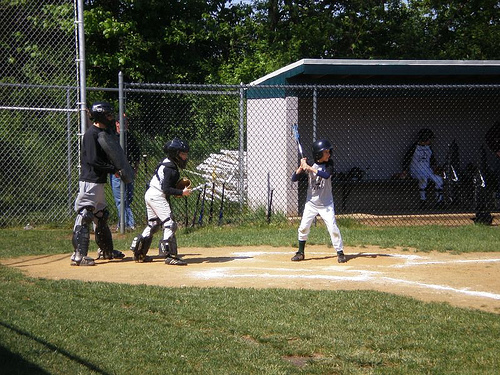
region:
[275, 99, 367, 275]
boy holding a baseball bat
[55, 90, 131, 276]
umpire wearing black and gray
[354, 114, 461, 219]
baseball player sitting in the dugout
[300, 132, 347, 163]
navy blue baseball helmet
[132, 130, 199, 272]
boy wearing catchers outfit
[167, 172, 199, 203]
brown catchers mitt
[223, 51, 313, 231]
gray and green wall of dugout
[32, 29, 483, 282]
boys playing baseball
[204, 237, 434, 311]
white lines in the dirt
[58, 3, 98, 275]
gray fence post around baseball field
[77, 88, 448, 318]
Baseball players on the field.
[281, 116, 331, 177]
Bat in boy's hand.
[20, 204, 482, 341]
Grass on the ground.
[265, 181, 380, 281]
White pants on the batter.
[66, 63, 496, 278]
Fence behind the field.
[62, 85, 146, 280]
Umpire behind the plate.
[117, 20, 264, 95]
Green trees behind field.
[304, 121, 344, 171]
Black helmet on the boy's head.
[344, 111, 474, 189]
Boys sitting on the bench.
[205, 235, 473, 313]
White markings on the dirt.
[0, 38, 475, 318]
a baseball game underway.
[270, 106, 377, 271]
a young person at bat.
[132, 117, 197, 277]
a ball player in catcher's gear.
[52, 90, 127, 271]
an umpire at a ball game.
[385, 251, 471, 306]
white lines on baseball field.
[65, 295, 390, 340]
patch of green grass on ball field.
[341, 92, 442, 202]
person sitting in baseball dugout.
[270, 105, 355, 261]
young ball player with baseball bat.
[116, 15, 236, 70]
a nice cluster of green trees.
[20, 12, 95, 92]
fence area on a field.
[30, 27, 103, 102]
silver batting tall fence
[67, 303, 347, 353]
light green cut grass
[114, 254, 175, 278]
tan baseball field dirt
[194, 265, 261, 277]
white chalk in dirt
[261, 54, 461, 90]
dark green and white building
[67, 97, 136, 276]
umpire behind catcher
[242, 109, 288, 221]
light gray stone wall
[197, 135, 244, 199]
silver pile of poles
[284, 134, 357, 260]
small boy batting at field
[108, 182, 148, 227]
woman in blue jeans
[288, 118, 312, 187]
Boy is holding baseball bat.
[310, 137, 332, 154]
Boy is wearing a helmet.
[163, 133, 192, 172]
Boy is wearing face guard.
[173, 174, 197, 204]
Boy is holding baseball mitt.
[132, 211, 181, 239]
Boy is wearing knee pads.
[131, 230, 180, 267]
Boy is wearing shin guards.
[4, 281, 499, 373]
The grass is green.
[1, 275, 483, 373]
The grass has been mowed.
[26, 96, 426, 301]
Boys are standing on dry dirt.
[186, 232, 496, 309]
There are chalk lines on the dirt.